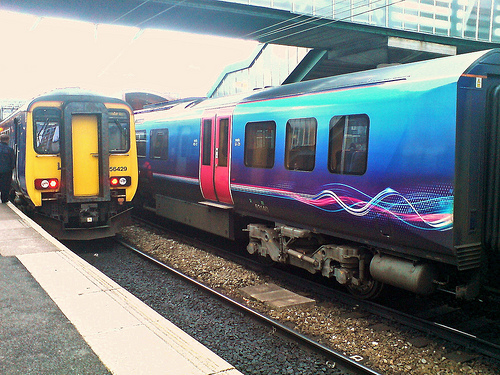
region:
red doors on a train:
[197, 106, 233, 206]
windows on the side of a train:
[240, 116, 380, 185]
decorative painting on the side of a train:
[301, 160, 458, 237]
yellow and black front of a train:
[19, 88, 149, 223]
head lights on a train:
[36, 175, 61, 192]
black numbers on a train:
[104, 160, 130, 175]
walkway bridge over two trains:
[269, 6, 457, 59]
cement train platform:
[4, 207, 121, 373]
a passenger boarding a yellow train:
[1, 128, 21, 220]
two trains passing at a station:
[12, 61, 494, 300]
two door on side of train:
[197, 100, 238, 211]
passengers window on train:
[241, 110, 281, 175]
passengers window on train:
[280, 108, 322, 178]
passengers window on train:
[322, 104, 377, 186]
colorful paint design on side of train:
[225, 168, 474, 254]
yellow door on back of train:
[67, 105, 105, 199]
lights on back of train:
[28, 177, 66, 194]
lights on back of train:
[105, 169, 137, 194]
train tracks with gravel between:
[115, 206, 339, 373]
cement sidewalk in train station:
[12, 226, 201, 369]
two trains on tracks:
[30, 127, 487, 337]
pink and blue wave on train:
[179, 162, 469, 237]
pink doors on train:
[177, 115, 242, 207]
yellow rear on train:
[21, 105, 131, 204]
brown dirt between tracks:
[138, 200, 421, 365]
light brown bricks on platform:
[15, 221, 175, 373]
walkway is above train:
[155, 1, 452, 68]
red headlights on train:
[39, 172, 129, 207]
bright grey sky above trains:
[48, 36, 102, 76]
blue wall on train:
[212, 94, 431, 238]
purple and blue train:
[136, 48, 499, 304]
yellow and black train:
[0, 92, 137, 241]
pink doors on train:
[201, 113, 231, 208]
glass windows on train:
[241, 113, 369, 177]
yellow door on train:
[70, 113, 102, 198]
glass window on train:
[35, 110, 64, 157]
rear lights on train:
[37, 178, 57, 190]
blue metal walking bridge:
[1, 4, 496, 48]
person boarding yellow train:
[2, 135, 17, 208]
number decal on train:
[475, 75, 481, 88]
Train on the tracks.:
[29, 77, 424, 259]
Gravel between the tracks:
[183, 247, 254, 302]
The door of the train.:
[84, 112, 117, 202]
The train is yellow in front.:
[29, 94, 116, 220]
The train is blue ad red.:
[176, 110, 461, 223]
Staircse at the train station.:
[182, 23, 326, 84]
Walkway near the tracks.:
[43, 235, 120, 372]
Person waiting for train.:
[2, 131, 24, 192]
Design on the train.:
[284, 174, 456, 222]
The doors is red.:
[194, 109, 230, 201]